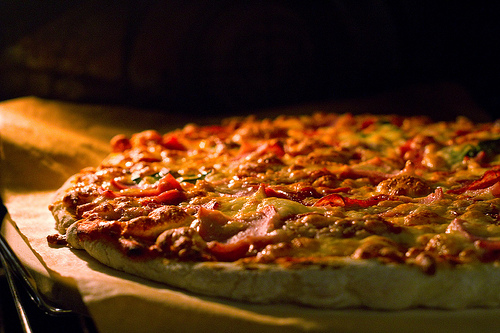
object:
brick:
[65, 23, 128, 83]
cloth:
[1, 94, 500, 333]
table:
[0, 100, 498, 331]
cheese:
[47, 111, 499, 309]